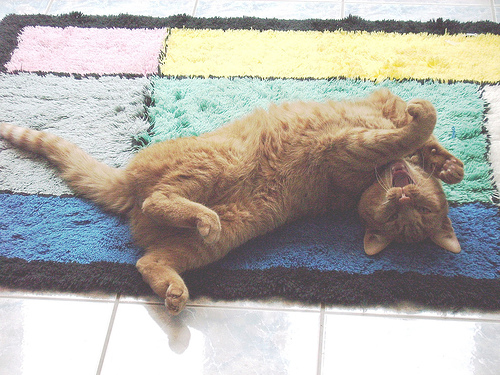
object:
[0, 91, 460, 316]
cat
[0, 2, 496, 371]
floor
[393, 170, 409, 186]
tongue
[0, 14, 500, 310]
rug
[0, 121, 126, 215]
tail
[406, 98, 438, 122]
paw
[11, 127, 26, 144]
stripes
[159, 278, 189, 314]
back paws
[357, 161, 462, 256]
head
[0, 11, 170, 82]
trim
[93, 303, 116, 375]
line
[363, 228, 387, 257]
ear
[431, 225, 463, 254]
ear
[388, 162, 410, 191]
mouth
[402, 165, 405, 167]
teeth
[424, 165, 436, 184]
whiskers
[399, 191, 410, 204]
nose